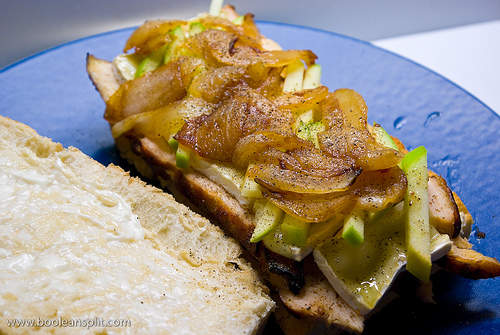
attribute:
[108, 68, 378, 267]
lunch — sandwich, open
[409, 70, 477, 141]
plate — blue, opaque, wet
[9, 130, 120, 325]
bread — sliced, white, toasted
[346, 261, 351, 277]
cheese — soft, white, melted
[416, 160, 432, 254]
apple — sliced, green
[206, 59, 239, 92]
onions — cooked, grilled, lunch, greasy, carmelized, brown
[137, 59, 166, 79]
green pepper — grilled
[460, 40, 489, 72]
table — white